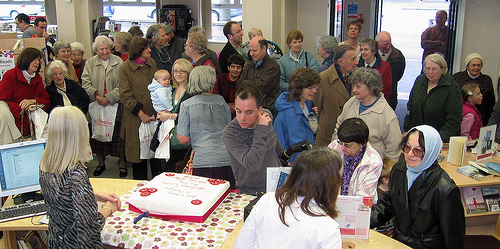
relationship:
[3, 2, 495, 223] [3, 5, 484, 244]
people in store